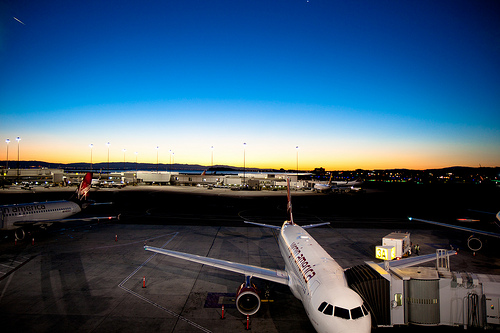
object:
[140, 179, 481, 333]
plane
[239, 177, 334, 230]
tail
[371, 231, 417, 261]
"the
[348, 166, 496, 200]
"a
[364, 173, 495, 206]
taxiway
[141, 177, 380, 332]
hood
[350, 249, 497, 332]
loading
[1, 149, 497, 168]
airway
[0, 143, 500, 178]
lights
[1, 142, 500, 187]
distance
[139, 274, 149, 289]
cone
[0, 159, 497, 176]
mountains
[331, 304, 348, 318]
cockpit window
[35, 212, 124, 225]
wing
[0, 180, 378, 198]
vehicle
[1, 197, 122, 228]
windows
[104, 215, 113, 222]
red light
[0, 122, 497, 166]
blue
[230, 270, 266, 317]
engine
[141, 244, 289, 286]
wings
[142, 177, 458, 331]
jet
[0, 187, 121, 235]
jet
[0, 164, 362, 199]
terminal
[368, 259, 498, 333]
jetway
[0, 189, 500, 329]
ground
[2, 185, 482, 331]
ground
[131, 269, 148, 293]
cone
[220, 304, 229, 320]
cone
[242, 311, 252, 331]
cone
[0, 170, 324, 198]
airport